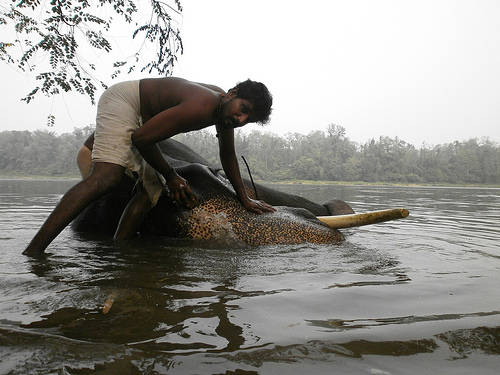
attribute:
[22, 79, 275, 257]
man — bending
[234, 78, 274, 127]
hair — black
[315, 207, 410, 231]
tusk — white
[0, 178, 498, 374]
water — brown, murky, rippling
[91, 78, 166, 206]
cloth — white